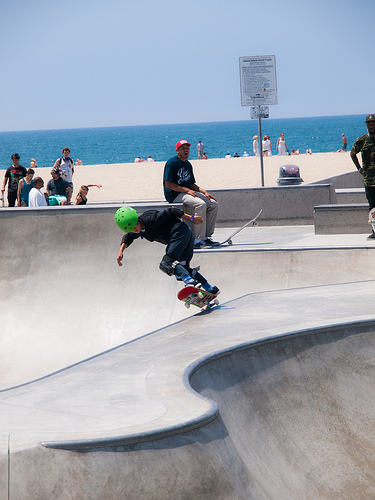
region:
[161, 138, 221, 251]
Man wearing red hat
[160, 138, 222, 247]
Man has mouth open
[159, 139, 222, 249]
Man is sitting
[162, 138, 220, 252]
Man stepping on skateboard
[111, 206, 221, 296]
Child riding skateboard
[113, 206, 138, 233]
Helmet on child is green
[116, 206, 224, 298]
Child wearing purple watch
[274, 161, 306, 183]
Trash can next to beach sign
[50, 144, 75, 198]
Man has blue headphones around neck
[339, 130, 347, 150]
Shirtless man walking by shore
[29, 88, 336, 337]
a child skateboarding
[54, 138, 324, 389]
a child is skateboarding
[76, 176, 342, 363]
a child wearing a green helmet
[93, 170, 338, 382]
a child skateboarding on a ramp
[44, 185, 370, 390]
a child at a park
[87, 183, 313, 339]
a child at a skate park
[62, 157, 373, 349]
a child wearing knee gaurds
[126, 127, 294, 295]
a man sittin gdown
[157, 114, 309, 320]
a man with one foot on skateboard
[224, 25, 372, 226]
a sign next to the ramps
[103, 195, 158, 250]
green hard helmet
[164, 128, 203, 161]
guy wearing a red cap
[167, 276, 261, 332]
red skate board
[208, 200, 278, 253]
boy with his foot on skate board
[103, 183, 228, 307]
guy wearing black shirt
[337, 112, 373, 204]
guy wearing camoflage shirt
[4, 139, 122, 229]
people sitting on the side walk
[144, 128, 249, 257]
guy sitting at skate park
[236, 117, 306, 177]
people wearing white on beach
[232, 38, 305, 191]
sign post on beach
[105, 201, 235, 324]
boy doing skateboard tricks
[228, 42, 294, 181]
black and white sign on pole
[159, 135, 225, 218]
man wearing a red baseball cup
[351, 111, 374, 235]
man in camouflage watching skateboarder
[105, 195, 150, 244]
skateboarder's neon green safety helmet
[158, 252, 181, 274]
skateboarder's black knee pads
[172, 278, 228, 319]
red and white skateboard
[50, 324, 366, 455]
concrete skateboard park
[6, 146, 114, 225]
crowd at the beach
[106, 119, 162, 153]
blue ocean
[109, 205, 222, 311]
Boy wearing green helmet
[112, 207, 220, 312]
Boy wearing black shirt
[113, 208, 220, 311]
Boy wearing black pants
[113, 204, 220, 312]
Boy wearing blue socks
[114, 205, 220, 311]
boy riding skate board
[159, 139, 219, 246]
Man wearing blue shirt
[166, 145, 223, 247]
Man wearing tan pants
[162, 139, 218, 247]
Man wearing black shoes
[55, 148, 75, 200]
Woman wearing white shirt